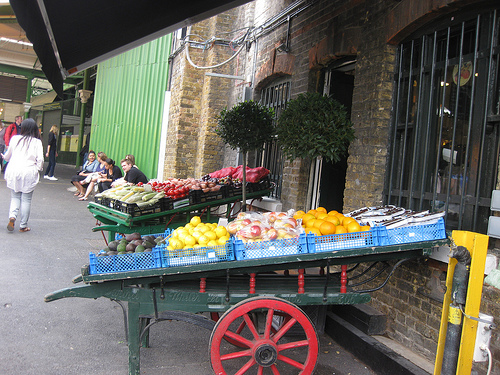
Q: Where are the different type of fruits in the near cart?
A: Blue crates.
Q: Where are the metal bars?
A: On the window.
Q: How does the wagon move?
A: It's wheels.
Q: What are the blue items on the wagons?
A: Crates.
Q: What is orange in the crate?
A: Oranges.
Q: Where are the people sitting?
A: Against a wall.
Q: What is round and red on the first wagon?
A: Wheel.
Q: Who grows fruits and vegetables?
A: Farmers.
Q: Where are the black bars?
A: Over the windows.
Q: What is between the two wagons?
A: Trees.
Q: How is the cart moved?
A: By wheels.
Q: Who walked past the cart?
A: A lady in white.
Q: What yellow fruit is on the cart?
A: Lemons.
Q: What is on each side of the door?
A: Plants.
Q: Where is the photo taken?
A: Farmers market.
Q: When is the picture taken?
A: During the day.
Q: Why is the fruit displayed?
A: To be sold.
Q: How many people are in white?
A: One.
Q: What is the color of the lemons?
A: Yellow.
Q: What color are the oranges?
A: Orange.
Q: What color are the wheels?
A: Red.